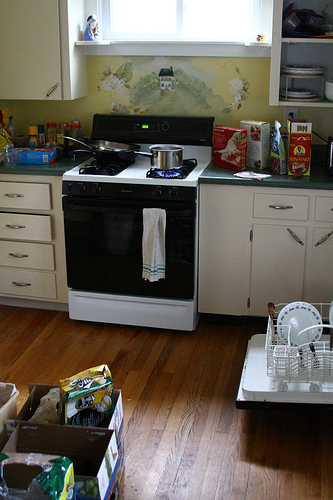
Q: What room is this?
A: It is a kitchen.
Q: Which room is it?
A: It is a kitchen.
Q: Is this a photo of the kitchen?
A: Yes, it is showing the kitchen.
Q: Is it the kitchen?
A: Yes, it is the kitchen.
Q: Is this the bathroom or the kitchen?
A: It is the kitchen.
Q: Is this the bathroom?
A: No, it is the kitchen.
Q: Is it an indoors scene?
A: Yes, it is indoors.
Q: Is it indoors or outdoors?
A: It is indoors.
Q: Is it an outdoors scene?
A: No, it is indoors.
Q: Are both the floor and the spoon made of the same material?
A: Yes, both the floor and the spoon are made of wood.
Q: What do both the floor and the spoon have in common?
A: The material, both the floor and the spoon are wooden.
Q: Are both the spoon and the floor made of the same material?
A: Yes, both the spoon and the floor are made of wood.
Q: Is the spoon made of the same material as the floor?
A: Yes, both the spoon and the floor are made of wood.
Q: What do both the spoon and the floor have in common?
A: The material, both the spoon and the floor are wooden.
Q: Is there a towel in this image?
A: Yes, there is a towel.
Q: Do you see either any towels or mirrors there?
A: Yes, there is a towel.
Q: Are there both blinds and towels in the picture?
A: No, there is a towel but no blinds.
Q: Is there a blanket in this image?
A: No, there are no blankets.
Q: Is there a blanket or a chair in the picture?
A: No, there are no blankets or chairs.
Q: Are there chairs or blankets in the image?
A: No, there are no blankets or chairs.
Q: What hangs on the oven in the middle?
A: The towel hangs on the oven.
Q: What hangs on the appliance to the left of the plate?
A: The towel hangs on the oven.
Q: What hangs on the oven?
A: The towel hangs on the oven.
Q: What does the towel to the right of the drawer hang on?
A: The towel hangs on the oven.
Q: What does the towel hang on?
A: The towel hangs on the oven.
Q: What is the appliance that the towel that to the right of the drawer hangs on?
A: The appliance is an oven.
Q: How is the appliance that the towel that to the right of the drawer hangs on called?
A: The appliance is an oven.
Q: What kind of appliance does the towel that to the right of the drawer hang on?
A: The towel hangs on the oven.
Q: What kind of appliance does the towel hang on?
A: The towel hangs on the oven.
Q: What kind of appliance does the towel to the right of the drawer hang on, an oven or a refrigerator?
A: The towel hangs on an oven.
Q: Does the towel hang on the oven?
A: Yes, the towel hangs on the oven.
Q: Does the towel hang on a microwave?
A: No, the towel hangs on the oven.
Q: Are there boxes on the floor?
A: Yes, there is a box on the floor.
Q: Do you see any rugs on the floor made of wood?
A: No, there is a box on the floor.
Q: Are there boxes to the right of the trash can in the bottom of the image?
A: Yes, there is a box to the right of the trash can.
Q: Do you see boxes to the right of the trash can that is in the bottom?
A: Yes, there is a box to the right of the trash can.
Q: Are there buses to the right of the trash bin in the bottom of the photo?
A: No, there is a box to the right of the garbage bin.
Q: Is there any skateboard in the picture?
A: No, there are no skateboards.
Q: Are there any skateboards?
A: No, there are no skateboards.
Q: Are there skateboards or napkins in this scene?
A: No, there are no skateboards or napkins.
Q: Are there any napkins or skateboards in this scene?
A: No, there are no skateboards or napkins.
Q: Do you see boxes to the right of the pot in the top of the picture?
A: Yes, there is a box to the right of the pot.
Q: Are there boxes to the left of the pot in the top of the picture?
A: No, the box is to the right of the pot.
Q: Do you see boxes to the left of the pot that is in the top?
A: No, the box is to the right of the pot.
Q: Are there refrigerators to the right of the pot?
A: No, there is a box to the right of the pot.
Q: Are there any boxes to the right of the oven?
A: Yes, there is a box to the right of the oven.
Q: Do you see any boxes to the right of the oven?
A: Yes, there is a box to the right of the oven.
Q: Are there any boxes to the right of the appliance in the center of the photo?
A: Yes, there is a box to the right of the oven.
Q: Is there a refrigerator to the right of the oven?
A: No, there is a box to the right of the oven.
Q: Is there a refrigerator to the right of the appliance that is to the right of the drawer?
A: No, there is a box to the right of the oven.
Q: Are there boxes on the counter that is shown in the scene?
A: Yes, there is a box on the counter.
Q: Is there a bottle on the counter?
A: No, there is a box on the counter.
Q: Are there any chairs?
A: No, there are no chairs.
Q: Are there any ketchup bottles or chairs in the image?
A: No, there are no chairs or ketchup bottles.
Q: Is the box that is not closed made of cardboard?
A: Yes, the box is made of cardboard.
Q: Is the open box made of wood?
A: No, the box is made of cardboard.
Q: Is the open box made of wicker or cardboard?
A: The box is made of cardboard.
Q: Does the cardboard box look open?
A: Yes, the box is open.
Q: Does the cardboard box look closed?
A: No, the box is open.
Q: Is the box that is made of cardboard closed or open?
A: The box is open.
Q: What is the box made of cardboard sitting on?
A: The box is sitting on the floor.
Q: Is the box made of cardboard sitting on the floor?
A: Yes, the box is sitting on the floor.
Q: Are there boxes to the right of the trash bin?
A: Yes, there is a box to the right of the trash bin.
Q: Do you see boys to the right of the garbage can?
A: No, there is a box to the right of the garbage can.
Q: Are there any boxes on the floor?
A: Yes, there is a box on the floor.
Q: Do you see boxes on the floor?
A: Yes, there is a box on the floor.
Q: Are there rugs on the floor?
A: No, there is a box on the floor.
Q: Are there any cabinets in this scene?
A: Yes, there is a cabinet.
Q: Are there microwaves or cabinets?
A: Yes, there is a cabinet.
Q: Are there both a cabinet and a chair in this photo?
A: No, there is a cabinet but no chairs.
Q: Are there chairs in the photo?
A: No, there are no chairs.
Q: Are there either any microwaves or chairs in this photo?
A: No, there are no chairs or microwaves.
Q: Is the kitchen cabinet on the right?
A: Yes, the cabinet is on the right of the image.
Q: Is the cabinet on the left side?
A: No, the cabinet is on the right of the image.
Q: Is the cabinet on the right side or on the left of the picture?
A: The cabinet is on the right of the image.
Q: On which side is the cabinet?
A: The cabinet is on the right of the image.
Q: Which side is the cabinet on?
A: The cabinet is on the right of the image.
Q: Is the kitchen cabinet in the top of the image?
A: Yes, the cabinet is in the top of the image.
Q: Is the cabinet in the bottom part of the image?
A: No, the cabinet is in the top of the image.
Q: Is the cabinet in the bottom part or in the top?
A: The cabinet is in the top of the image.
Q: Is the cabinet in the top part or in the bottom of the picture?
A: The cabinet is in the top of the image.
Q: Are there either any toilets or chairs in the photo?
A: No, there are no chairs or toilets.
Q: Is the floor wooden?
A: Yes, the floor is wooden.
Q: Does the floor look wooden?
A: Yes, the floor is wooden.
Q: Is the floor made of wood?
A: Yes, the floor is made of wood.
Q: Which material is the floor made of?
A: The floor is made of wood.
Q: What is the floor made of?
A: The floor is made of wood.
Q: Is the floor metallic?
A: No, the floor is wooden.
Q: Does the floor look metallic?
A: No, the floor is wooden.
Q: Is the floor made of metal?
A: No, the floor is made of wood.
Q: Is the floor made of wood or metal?
A: The floor is made of wood.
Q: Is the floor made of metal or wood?
A: The floor is made of wood.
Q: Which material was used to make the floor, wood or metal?
A: The floor is made of wood.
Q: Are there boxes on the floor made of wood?
A: Yes, there is a box on the floor.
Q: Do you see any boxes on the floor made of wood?
A: Yes, there is a box on the floor.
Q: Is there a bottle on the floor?
A: No, there is a box on the floor.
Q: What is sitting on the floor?
A: The box is sitting on the floor.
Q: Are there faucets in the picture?
A: No, there are no faucets.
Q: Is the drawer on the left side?
A: Yes, the drawer is on the left of the image.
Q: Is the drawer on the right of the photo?
A: No, the drawer is on the left of the image.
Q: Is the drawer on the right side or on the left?
A: The drawer is on the left of the image.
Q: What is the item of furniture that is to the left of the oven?
A: The piece of furniture is a drawer.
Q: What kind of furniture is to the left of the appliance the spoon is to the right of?
A: The piece of furniture is a drawer.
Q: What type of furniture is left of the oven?
A: The piece of furniture is a drawer.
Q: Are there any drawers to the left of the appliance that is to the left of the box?
A: Yes, there is a drawer to the left of the oven.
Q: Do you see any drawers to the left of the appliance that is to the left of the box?
A: Yes, there is a drawer to the left of the oven.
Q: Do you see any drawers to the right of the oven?
A: No, the drawer is to the left of the oven.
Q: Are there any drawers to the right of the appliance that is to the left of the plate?
A: No, the drawer is to the left of the oven.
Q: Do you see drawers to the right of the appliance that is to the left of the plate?
A: No, the drawer is to the left of the oven.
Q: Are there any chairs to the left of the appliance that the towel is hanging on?
A: No, there is a drawer to the left of the oven.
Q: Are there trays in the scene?
A: No, there are no trays.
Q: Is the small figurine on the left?
A: Yes, the figurine is on the left of the image.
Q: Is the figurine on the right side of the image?
A: No, the figurine is on the left of the image.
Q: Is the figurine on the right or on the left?
A: The figurine is on the left of the image.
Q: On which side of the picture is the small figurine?
A: The figurine is on the left of the image.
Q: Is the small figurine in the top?
A: Yes, the figurine is in the top of the image.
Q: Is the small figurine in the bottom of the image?
A: No, the figurine is in the top of the image.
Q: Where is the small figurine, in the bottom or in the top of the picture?
A: The figurine is in the top of the image.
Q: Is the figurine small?
A: Yes, the figurine is small.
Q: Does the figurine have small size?
A: Yes, the figurine is small.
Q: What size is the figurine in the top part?
A: The figurine is small.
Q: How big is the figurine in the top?
A: The figurine is small.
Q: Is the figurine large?
A: No, the figurine is small.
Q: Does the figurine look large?
A: No, the figurine is small.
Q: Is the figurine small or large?
A: The figurine is small.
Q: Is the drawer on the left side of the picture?
A: Yes, the drawer is on the left of the image.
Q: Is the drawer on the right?
A: No, the drawer is on the left of the image.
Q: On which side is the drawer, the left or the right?
A: The drawer is on the left of the image.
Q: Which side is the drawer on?
A: The drawer is on the left of the image.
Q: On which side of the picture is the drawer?
A: The drawer is on the left of the image.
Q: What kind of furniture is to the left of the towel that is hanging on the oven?
A: The piece of furniture is a drawer.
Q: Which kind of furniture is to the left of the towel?
A: The piece of furniture is a drawer.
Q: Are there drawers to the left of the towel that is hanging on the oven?
A: Yes, there is a drawer to the left of the towel.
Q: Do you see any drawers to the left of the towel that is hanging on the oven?
A: Yes, there is a drawer to the left of the towel.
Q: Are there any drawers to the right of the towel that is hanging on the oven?
A: No, the drawer is to the left of the towel.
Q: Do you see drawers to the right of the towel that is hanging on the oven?
A: No, the drawer is to the left of the towel.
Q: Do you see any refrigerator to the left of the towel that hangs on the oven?
A: No, there is a drawer to the left of the towel.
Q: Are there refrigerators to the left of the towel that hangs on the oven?
A: No, there is a drawer to the left of the towel.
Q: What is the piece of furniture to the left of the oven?
A: The piece of furniture is a drawer.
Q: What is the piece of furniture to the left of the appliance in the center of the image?
A: The piece of furniture is a drawer.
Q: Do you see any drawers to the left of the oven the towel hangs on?
A: Yes, there is a drawer to the left of the oven.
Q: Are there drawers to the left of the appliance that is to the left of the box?
A: Yes, there is a drawer to the left of the oven.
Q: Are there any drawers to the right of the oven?
A: No, the drawer is to the left of the oven.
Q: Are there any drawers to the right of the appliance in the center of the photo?
A: No, the drawer is to the left of the oven.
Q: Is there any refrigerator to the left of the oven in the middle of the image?
A: No, there is a drawer to the left of the oven.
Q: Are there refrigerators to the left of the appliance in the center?
A: No, there is a drawer to the left of the oven.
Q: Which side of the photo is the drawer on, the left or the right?
A: The drawer is on the left of the image.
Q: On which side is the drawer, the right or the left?
A: The drawer is on the left of the image.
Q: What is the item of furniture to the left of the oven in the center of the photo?
A: The piece of furniture is a drawer.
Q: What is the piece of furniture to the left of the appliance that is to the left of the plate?
A: The piece of furniture is a drawer.